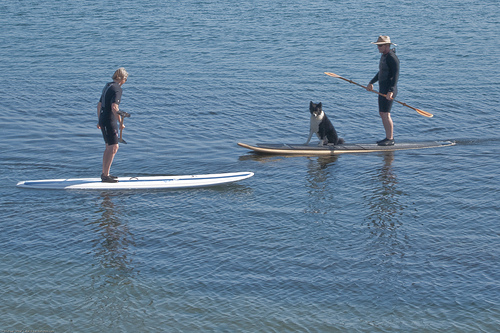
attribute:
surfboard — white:
[15, 168, 254, 196]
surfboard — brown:
[235, 132, 464, 156]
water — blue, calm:
[5, 192, 499, 331]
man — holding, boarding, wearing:
[367, 33, 402, 149]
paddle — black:
[322, 66, 438, 121]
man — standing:
[98, 66, 134, 186]